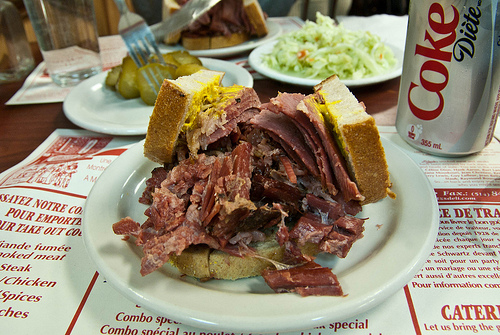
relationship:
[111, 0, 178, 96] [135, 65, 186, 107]
fork stabbed in food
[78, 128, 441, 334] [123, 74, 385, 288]
plate of food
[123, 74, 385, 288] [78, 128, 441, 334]
food on plate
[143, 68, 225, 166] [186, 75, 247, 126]
bread with mustard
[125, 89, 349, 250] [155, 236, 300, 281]
meat on bread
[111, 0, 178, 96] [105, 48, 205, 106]
fork in pickles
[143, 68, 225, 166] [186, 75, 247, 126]
bread has mustard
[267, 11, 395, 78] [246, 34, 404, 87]
lettuce on plate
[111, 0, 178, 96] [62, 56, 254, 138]
fork on plate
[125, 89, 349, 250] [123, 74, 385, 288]
meat in sandwich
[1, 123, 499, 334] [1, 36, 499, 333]
mat on top of table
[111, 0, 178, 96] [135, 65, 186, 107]
fork in food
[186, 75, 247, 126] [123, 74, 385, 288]
mustard on food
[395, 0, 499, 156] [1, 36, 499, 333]
can on table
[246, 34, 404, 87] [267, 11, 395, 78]
plate of lettuce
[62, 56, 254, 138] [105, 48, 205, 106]
plate of pickles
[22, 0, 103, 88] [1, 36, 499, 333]
glass on table